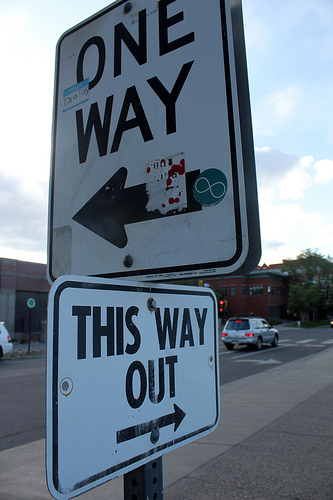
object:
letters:
[76, 34, 107, 92]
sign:
[42, 0, 264, 290]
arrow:
[70, 165, 204, 250]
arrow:
[116, 401, 187, 445]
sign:
[42, 268, 223, 500]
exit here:
[65, 301, 211, 444]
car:
[219, 314, 281, 352]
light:
[219, 300, 224, 306]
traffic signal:
[219, 308, 223, 313]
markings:
[230, 357, 284, 365]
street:
[0, 325, 333, 500]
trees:
[312, 257, 321, 282]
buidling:
[247, 262, 288, 322]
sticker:
[192, 166, 228, 208]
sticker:
[62, 77, 90, 113]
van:
[0, 321, 15, 361]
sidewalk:
[0, 352, 332, 500]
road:
[0, 324, 332, 500]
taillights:
[245, 333, 254, 337]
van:
[220, 314, 281, 352]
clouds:
[253, 146, 315, 201]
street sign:
[44, 0, 263, 286]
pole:
[122, 455, 164, 500]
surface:
[0, 343, 332, 500]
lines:
[229, 347, 282, 360]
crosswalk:
[278, 334, 332, 346]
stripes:
[293, 337, 318, 345]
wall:
[0, 254, 45, 348]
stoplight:
[219, 300, 224, 305]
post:
[220, 278, 227, 323]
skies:
[0, 0, 333, 266]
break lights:
[222, 332, 229, 336]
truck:
[221, 316, 281, 352]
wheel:
[256, 338, 263, 352]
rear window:
[226, 319, 249, 331]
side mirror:
[269, 324, 275, 328]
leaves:
[301, 292, 308, 302]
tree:
[295, 287, 311, 308]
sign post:
[45, 271, 225, 500]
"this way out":
[69, 302, 209, 410]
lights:
[219, 308, 223, 313]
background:
[0, 1, 332, 358]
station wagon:
[220, 313, 281, 352]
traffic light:
[219, 300, 224, 306]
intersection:
[219, 318, 333, 354]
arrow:
[228, 357, 284, 365]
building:
[214, 272, 250, 318]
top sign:
[44, 0, 264, 286]